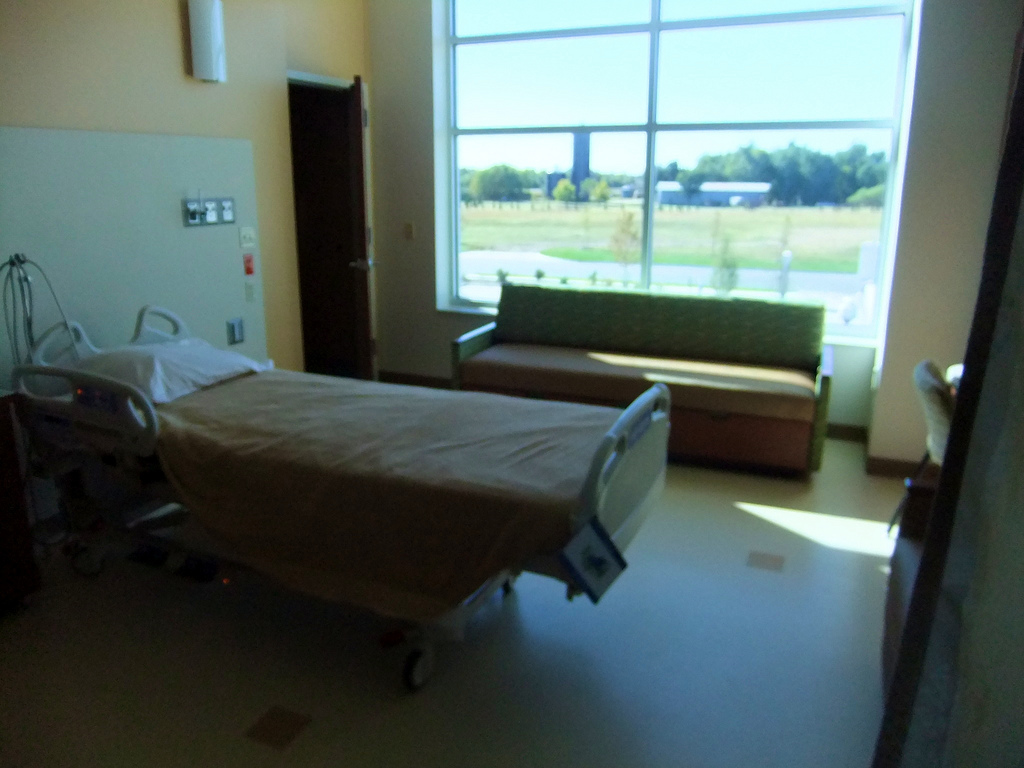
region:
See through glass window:
[508, 72, 850, 263]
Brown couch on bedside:
[445, 296, 844, 396]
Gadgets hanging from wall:
[13, 246, 81, 345]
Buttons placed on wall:
[177, 186, 257, 241]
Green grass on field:
[533, 199, 613, 242]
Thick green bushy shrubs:
[790, 143, 857, 202]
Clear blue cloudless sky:
[726, 57, 870, 105]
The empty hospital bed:
[8, 295, 692, 684]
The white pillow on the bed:
[57, 328, 279, 411]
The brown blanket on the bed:
[152, 355, 634, 583]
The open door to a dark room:
[279, 67, 396, 388]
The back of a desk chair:
[873, 354, 959, 532]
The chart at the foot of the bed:
[563, 516, 636, 612]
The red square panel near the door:
[239, 247, 263, 283]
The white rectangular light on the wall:
[182, 4, 234, 88]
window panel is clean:
[655, 10, 911, 124]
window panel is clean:
[453, 4, 657, 40]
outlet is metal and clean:
[221, 196, 235, 222]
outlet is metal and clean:
[202, 197, 221, 224]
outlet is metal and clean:
[184, 197, 203, 224]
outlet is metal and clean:
[226, 319, 245, 340]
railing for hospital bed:
[18, 372, 149, 436]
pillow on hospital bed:
[87, 339, 193, 384]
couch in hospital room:
[498, 291, 819, 390]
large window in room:
[443, 9, 890, 270]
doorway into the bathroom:
[305, 95, 372, 361]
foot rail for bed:
[588, 395, 680, 501]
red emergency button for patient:
[242, 258, 258, 279]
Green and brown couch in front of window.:
[454, 276, 853, 431]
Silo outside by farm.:
[569, 126, 598, 197]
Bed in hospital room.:
[20, 301, 675, 701]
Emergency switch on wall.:
[238, 249, 258, 276]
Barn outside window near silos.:
[652, 172, 774, 211]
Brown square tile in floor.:
[738, 545, 790, 578]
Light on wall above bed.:
[175, 0, 234, 85]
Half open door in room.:
[279, 68, 385, 379]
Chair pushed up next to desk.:
[890, 353, 957, 532]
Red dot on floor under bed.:
[210, 570, 245, 591]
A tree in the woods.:
[482, 162, 527, 197]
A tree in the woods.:
[467, 169, 486, 204]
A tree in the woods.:
[555, 177, 574, 204]